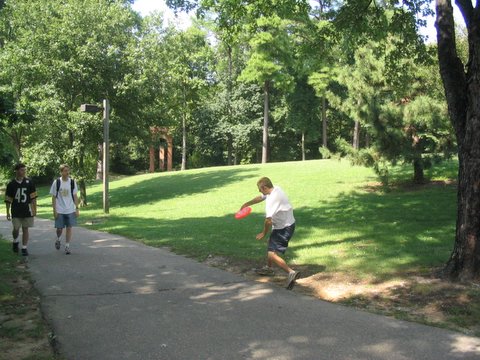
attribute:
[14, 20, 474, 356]
park — scene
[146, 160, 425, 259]
lawn — green 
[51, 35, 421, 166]
trees — some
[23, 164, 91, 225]
people —  walking 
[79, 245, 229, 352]
sidewalk —  gray 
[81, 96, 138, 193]
pole — light  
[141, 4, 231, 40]
sky — white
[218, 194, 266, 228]
frisbee — red 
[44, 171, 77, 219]
backpack — black  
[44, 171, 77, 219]
straps — black backpack 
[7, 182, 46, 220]
jersey — black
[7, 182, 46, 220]
number — white 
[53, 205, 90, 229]
shorts — jean 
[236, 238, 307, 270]
shorts —  black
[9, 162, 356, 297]
men — three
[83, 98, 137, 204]
pole — silver metal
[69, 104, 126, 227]
fixture — light 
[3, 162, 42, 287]
jersey — black 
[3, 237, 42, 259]
shoes — black 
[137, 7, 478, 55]
sky — daytime , light 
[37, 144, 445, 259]
slope — grassy 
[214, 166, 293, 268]
frisbee — red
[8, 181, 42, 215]
number — white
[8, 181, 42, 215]
jersey — sports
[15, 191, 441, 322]
walkway — paved